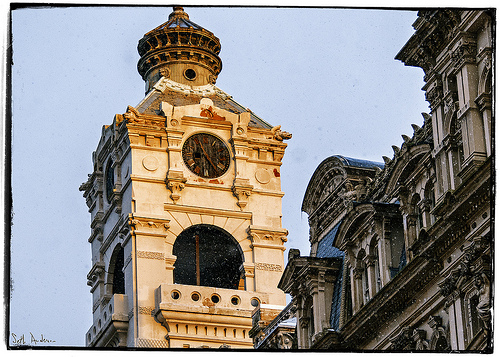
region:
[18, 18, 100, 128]
the sky is blue and clear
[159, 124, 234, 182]
clock on the tower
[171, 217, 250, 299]
arch under the clock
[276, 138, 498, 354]
building beside the tower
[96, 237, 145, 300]
arch on the tower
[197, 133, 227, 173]
hands of the clock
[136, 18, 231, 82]
top of the tower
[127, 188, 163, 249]
corner of the tower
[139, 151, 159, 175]
circle on the tower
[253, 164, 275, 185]
circle on the tower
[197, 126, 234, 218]
There is a clock that is visible here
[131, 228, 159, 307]
There is light concrete here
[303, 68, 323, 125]
There is a light blue sky here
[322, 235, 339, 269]
There is a blue color on this building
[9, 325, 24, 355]
The name on this photo is "Seth"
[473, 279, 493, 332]
There is a sculpture on this building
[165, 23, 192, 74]
There is an ornate tower here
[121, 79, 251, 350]
This photo has a great deal of detail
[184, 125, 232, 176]
clock on side of tower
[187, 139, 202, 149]
numbers on side of clock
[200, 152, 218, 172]
long hand on clock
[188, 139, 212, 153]
short hand on clock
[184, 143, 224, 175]
black face of clock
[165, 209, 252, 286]
archway on side of building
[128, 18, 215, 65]
dome on top of building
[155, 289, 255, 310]
small holes on side of building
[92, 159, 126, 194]
clock on side of building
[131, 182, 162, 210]
white stone structure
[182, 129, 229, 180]
clock on the building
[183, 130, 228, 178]
the clock looks rusted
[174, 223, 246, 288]
an arch shaped opening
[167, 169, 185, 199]
carving on the wall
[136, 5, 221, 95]
a fancy looking tower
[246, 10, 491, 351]
the building looks fancy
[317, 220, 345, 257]
blue tiles on wall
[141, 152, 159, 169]
circle on the wall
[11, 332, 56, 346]
name in the corner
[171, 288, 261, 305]
five circular openings